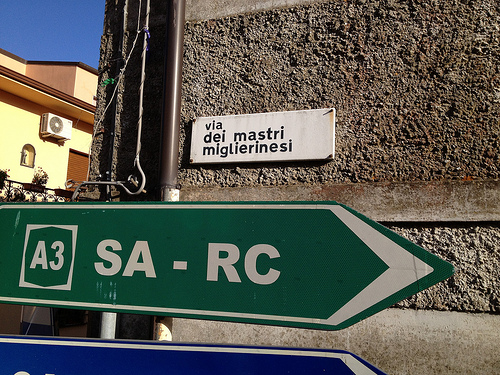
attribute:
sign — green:
[0, 173, 451, 326]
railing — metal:
[11, 170, 47, 197]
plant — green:
[33, 167, 52, 190]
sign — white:
[178, 87, 343, 182]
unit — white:
[34, 114, 71, 141]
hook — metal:
[105, 3, 149, 203]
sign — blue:
[0, 327, 413, 373]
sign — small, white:
[185, 104, 339, 163]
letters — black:
[199, 126, 294, 157]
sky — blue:
[11, 11, 97, 49]